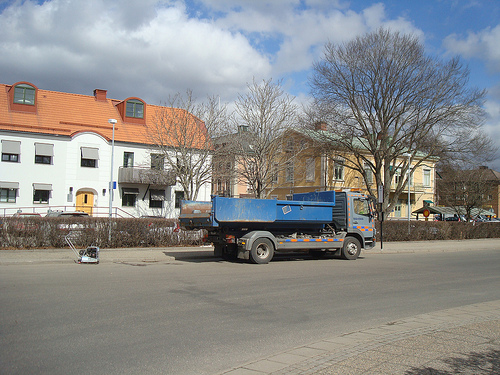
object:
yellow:
[76, 191, 93, 217]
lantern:
[108, 119, 117, 125]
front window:
[353, 199, 370, 216]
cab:
[333, 192, 376, 250]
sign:
[377, 185, 384, 249]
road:
[0, 250, 499, 375]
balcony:
[118, 167, 176, 185]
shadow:
[404, 348, 500, 375]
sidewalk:
[1, 239, 500, 375]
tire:
[249, 238, 274, 264]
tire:
[341, 236, 361, 260]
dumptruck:
[179, 188, 377, 264]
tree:
[305, 24, 500, 220]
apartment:
[0, 81, 217, 218]